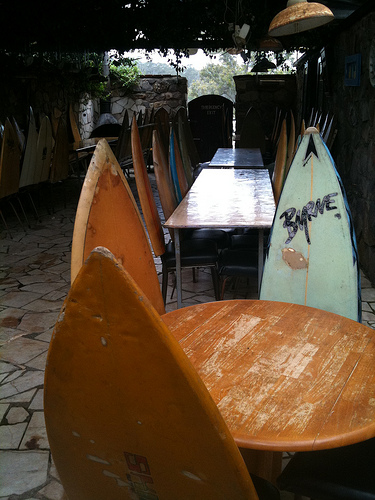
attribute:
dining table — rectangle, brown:
[158, 164, 282, 301]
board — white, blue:
[256, 122, 369, 320]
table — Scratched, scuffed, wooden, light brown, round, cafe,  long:
[149, 295, 374, 452]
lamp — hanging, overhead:
[265, 0, 340, 40]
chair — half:
[143, 118, 222, 298]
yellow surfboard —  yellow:
[43, 243, 260, 498]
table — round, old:
[156, 295, 373, 498]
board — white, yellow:
[255, 122, 357, 320]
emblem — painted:
[300, 137, 324, 168]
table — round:
[218, 280, 305, 342]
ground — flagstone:
[11, 228, 56, 334]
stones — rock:
[0, 208, 75, 336]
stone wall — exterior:
[2, 75, 187, 144]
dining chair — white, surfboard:
[256, 128, 358, 322]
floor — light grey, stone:
[1, 173, 373, 496]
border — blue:
[170, 123, 184, 197]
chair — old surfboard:
[124, 112, 224, 300]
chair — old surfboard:
[148, 126, 200, 244]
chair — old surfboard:
[164, 115, 195, 201]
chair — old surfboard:
[174, 112, 198, 180]